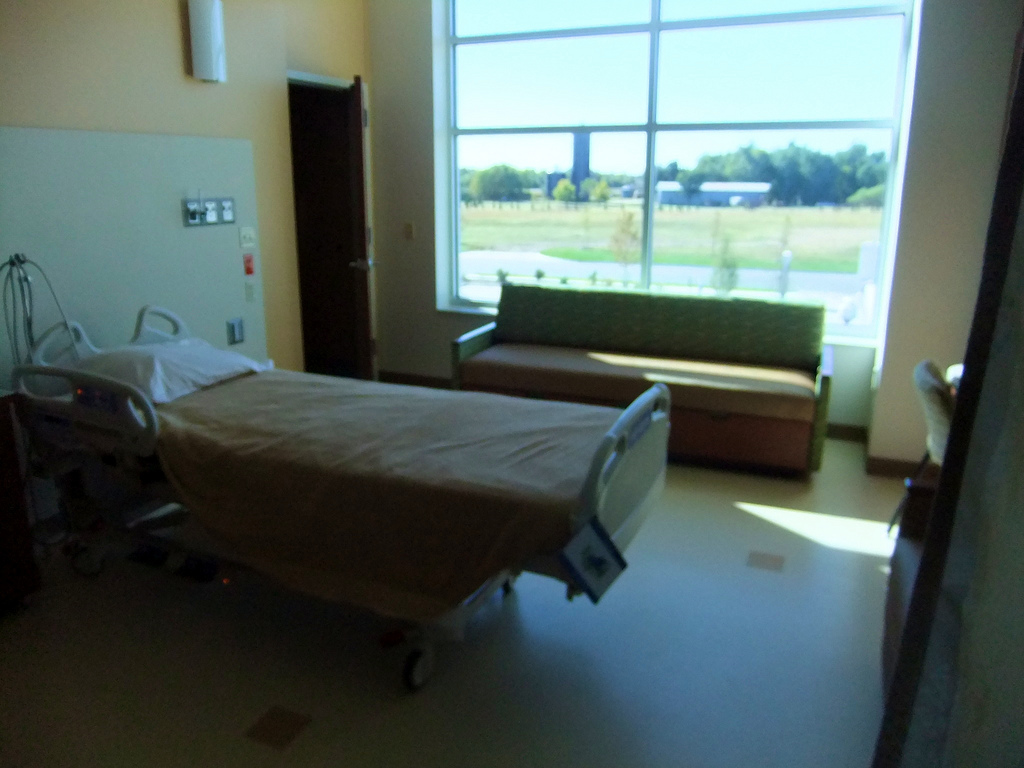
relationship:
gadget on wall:
[6, 257, 64, 327] [5, 5, 303, 370]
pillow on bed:
[71, 307, 262, 415] [10, 275, 693, 601]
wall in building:
[0, 0, 380, 401] [15, 9, 1014, 764]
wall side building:
[48, 117, 175, 216] [15, 9, 1014, 764]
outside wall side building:
[863, 0, 1024, 475] [15, 9, 1014, 764]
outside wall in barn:
[863, 0, 1024, 475] [654, 180, 772, 207]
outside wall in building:
[863, 0, 1024, 475] [15, 9, 1014, 764]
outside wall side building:
[370, 8, 435, 367] [15, 9, 1014, 764]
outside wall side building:
[895, 10, 971, 444] [15, 9, 1014, 764]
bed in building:
[0, 296, 678, 696] [0, 0, 1024, 768]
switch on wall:
[231, 247, 277, 295] [215, 221, 289, 327]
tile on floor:
[730, 540, 794, 582] [6, 475, 926, 766]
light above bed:
[167, 0, 244, 90] [9, 273, 695, 657]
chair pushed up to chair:
[891, 354, 975, 551] [889, 360, 976, 535]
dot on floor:
[208, 559, 241, 597] [6, 475, 926, 766]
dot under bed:
[208, 559, 241, 597] [6, 282, 926, 707]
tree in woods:
[483, 156, 534, 213] [457, 121, 901, 211]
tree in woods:
[460, 159, 492, 207] [452, 129, 906, 207]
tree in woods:
[549, 171, 576, 204] [457, 121, 901, 211]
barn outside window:
[650, 168, 784, 232] [439, 0, 926, 336]